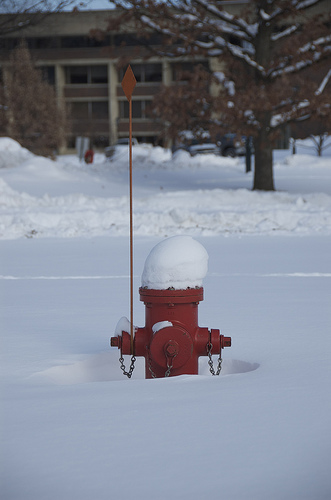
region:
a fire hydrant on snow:
[101, 60, 240, 383]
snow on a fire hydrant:
[129, 224, 216, 314]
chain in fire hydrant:
[199, 321, 238, 381]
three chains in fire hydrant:
[104, 324, 241, 387]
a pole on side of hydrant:
[111, 55, 151, 351]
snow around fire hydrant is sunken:
[35, 225, 272, 400]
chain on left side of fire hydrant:
[115, 337, 141, 389]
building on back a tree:
[3, 3, 256, 157]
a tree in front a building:
[110, 2, 329, 197]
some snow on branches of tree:
[123, 2, 329, 201]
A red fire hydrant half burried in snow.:
[109, 229, 233, 394]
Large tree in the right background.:
[126, 2, 328, 192]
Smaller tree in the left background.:
[1, 35, 62, 157]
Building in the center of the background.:
[13, 9, 227, 161]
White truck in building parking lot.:
[183, 134, 222, 158]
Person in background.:
[81, 143, 97, 167]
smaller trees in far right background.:
[290, 126, 330, 166]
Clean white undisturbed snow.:
[6, 377, 325, 495]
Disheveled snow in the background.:
[1, 177, 327, 239]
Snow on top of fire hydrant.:
[138, 233, 212, 285]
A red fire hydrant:
[112, 235, 232, 384]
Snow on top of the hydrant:
[137, 229, 206, 290]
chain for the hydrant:
[112, 348, 139, 383]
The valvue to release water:
[220, 327, 232, 355]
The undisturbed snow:
[126, 426, 239, 494]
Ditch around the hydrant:
[55, 340, 258, 387]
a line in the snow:
[11, 269, 126, 286]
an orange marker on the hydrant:
[122, 55, 140, 354]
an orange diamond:
[119, 59, 137, 103]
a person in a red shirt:
[82, 142, 99, 168]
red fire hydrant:
[130, 284, 226, 379]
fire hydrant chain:
[205, 340, 229, 380]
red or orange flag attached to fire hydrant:
[109, 60, 155, 361]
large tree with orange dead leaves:
[133, 3, 329, 195]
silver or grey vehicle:
[179, 128, 219, 160]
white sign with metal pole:
[72, 127, 100, 171]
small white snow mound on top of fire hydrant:
[137, 226, 215, 296]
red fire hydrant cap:
[147, 317, 198, 376]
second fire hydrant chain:
[104, 335, 142, 380]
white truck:
[97, 129, 164, 163]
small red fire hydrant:
[126, 215, 234, 401]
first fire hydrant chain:
[107, 324, 141, 382]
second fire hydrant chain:
[203, 333, 240, 380]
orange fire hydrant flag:
[112, 56, 152, 366]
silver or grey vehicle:
[163, 115, 223, 167]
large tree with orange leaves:
[167, 7, 323, 208]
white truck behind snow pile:
[104, 133, 160, 171]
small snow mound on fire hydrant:
[140, 226, 214, 304]